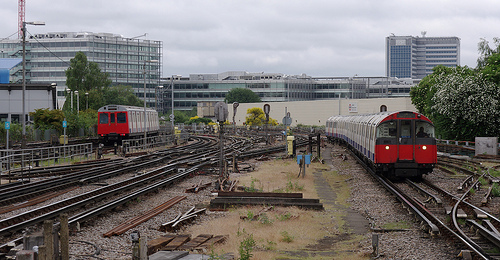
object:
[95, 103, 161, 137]
train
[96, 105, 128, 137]
front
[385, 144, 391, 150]
headlight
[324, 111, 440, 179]
train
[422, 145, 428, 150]
headlight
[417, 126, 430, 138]
conductor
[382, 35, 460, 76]
building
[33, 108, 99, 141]
shrubs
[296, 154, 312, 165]
sign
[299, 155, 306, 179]
post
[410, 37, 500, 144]
trees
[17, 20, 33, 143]
light pole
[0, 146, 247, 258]
tracks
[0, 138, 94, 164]
fence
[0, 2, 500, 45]
sky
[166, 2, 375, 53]
clouds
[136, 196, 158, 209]
gravel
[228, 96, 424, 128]
wall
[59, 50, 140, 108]
trees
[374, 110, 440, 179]
front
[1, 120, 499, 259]
train yard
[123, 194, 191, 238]
slat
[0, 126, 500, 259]
ground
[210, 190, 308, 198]
slats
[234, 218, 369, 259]
dirt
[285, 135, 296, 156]
pole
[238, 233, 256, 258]
grass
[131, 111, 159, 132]
edge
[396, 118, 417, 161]
door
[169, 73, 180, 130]
post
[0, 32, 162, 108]
building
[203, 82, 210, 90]
window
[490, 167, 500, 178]
grass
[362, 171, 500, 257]
tracks